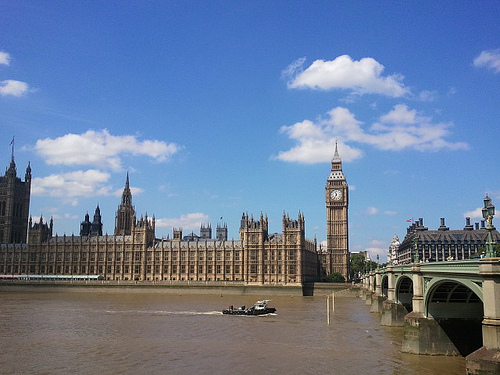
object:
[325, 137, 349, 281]
clocktower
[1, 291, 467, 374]
water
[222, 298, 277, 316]
boat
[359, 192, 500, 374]
bridge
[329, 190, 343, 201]
clock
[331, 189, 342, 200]
time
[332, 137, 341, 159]
point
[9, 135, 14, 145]
flag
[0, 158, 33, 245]
building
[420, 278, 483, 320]
arches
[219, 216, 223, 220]
flag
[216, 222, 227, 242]
building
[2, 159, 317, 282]
house of parliament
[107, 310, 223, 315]
trail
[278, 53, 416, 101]
clouds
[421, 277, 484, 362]
passeges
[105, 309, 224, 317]
wake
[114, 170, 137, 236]
towers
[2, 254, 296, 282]
windows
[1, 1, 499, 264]
sky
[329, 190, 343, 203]
white face